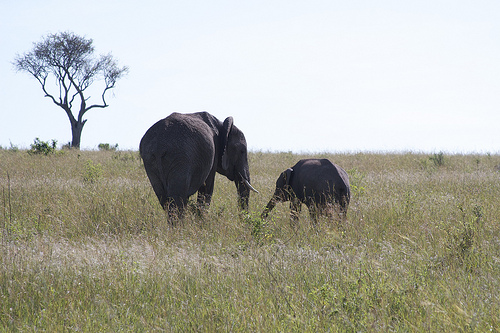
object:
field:
[0, 154, 500, 333]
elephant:
[138, 111, 260, 228]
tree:
[9, 29, 130, 149]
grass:
[0, 149, 500, 333]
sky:
[0, 1, 500, 153]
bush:
[427, 151, 447, 167]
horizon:
[0, 137, 500, 164]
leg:
[164, 173, 190, 226]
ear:
[221, 116, 233, 171]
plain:
[0, 149, 500, 333]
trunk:
[235, 167, 251, 210]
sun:
[326, 20, 448, 115]